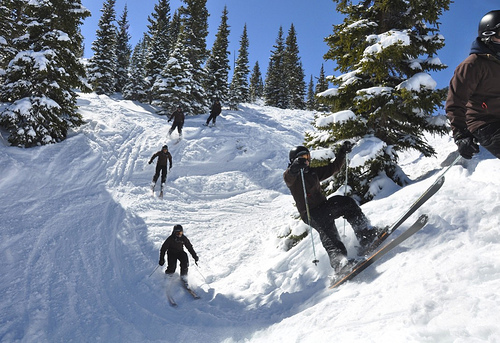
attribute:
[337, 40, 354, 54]
leaf — IS GREEN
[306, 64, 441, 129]
leaf — IS GREEN